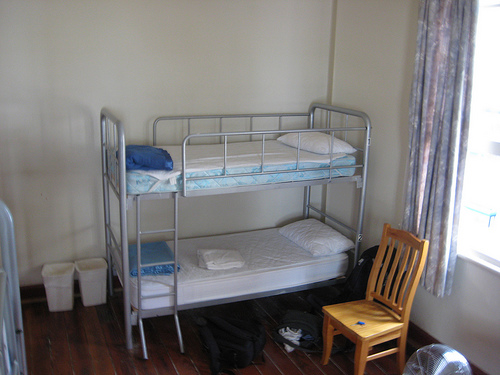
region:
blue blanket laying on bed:
[117, 132, 180, 192]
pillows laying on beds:
[266, 120, 358, 263]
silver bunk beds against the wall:
[77, 92, 384, 361]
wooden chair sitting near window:
[311, 201, 498, 373]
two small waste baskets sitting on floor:
[37, 240, 107, 336]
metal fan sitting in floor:
[368, 340, 483, 373]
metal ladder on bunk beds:
[117, 185, 194, 372]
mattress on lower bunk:
[113, 217, 346, 317]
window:
[442, 17, 498, 277]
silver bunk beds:
[75, 101, 381, 361]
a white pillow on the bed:
[280, 125, 355, 165]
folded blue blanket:
[120, 235, 180, 285]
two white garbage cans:
[32, 245, 112, 315]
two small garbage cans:
[35, 250, 125, 315]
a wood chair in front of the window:
[308, 215, 498, 370]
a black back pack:
[186, 305, 262, 370]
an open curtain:
[388, 0, 488, 293]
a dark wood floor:
[35, 305, 300, 371]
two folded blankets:
[113, 125, 185, 290]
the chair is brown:
[318, 220, 423, 370]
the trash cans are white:
[36, 262, 108, 315]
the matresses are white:
[217, 236, 300, 270]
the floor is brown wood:
[63, 334, 105, 352]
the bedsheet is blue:
[131, 241, 176, 270]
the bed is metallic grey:
[11, 220, 33, 370]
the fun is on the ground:
[421, 342, 466, 373]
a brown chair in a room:
[320, 212, 438, 373]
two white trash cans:
[31, 247, 113, 318]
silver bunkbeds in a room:
[75, 77, 386, 367]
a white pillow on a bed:
[266, 201, 363, 272]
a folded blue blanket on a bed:
[112, 132, 180, 194]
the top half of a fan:
[388, 330, 475, 371]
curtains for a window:
[396, 3, 488, 314]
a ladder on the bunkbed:
[125, 160, 200, 361]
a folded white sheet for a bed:
[186, 234, 259, 286]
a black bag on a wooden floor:
[266, 296, 331, 358]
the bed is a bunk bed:
[97, 97, 373, 362]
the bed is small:
[93, 97, 363, 361]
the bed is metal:
[99, 100, 371, 362]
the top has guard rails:
[152, 108, 368, 181]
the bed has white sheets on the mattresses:
[110, 132, 351, 312]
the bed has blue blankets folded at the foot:
[113, 139, 186, 284]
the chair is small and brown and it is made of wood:
[313, 218, 430, 373]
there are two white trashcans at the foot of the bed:
[38, 249, 109, 317]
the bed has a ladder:
[132, 188, 183, 363]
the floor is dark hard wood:
[3, 280, 498, 373]